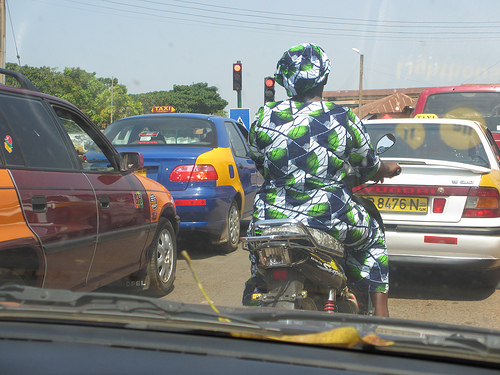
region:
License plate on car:
[361, 195, 426, 215]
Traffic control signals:
[228, 59, 275, 102]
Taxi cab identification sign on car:
[146, 103, 178, 114]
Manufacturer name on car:
[355, 183, 439, 195]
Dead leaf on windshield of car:
[179, 251, 389, 351]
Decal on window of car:
[1, 133, 17, 155]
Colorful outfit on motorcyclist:
[244, 46, 394, 292]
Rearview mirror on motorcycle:
[370, 132, 402, 157]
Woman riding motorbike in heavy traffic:
[242, 41, 401, 318]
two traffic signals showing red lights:
[229, 57, 278, 109]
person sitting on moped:
[240, 47, 392, 322]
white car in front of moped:
[360, 111, 499, 253]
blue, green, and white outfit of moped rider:
[237, 38, 392, 294]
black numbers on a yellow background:
[377, 193, 406, 212]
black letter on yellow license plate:
[406, 196, 421, 213]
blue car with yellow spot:
[101, 116, 264, 236]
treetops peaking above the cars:
[22, 58, 219, 119]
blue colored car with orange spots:
[2, 83, 190, 299]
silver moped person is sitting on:
[233, 203, 387, 321]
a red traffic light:
[257, 65, 285, 135]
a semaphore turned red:
[258, 62, 285, 122]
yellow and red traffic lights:
[214, 35, 302, 140]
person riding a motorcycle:
[228, 33, 416, 340]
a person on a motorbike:
[238, 29, 418, 358]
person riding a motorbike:
[228, 32, 413, 333]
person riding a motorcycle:
[222, 35, 407, 330]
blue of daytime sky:
[7, 3, 497, 110]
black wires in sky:
[72, 0, 496, 42]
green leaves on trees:
[4, 64, 229, 121]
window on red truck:
[416, 85, 497, 141]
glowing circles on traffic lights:
[232, 63, 275, 103]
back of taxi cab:
[363, 112, 498, 291]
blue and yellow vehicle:
[82, 112, 262, 253]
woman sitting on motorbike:
[236, 42, 399, 314]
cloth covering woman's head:
[274, 44, 330, 96]